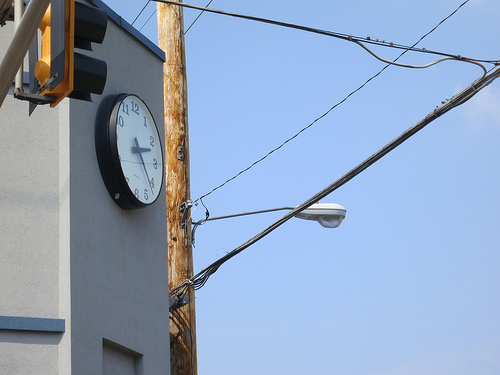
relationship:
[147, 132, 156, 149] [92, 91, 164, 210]
number written on clock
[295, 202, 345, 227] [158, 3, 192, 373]
light on pole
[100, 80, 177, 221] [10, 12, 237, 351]
clock on building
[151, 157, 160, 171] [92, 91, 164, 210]
3 on clock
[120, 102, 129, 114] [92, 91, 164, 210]
number 11 on clock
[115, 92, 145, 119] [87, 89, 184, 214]
numbers on clock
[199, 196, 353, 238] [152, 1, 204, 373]
lamp on pole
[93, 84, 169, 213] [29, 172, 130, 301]
clock on building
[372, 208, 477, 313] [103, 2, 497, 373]
clouds in sky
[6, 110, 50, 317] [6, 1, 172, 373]
gray side in sunlight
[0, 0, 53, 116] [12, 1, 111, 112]
pole holding stop light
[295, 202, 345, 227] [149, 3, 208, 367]
light attached to pole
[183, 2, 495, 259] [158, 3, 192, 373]
power lines on pole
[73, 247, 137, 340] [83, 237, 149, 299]
decoration on wall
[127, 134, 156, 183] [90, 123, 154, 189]
handle on clock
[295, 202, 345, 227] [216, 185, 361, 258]
light on street light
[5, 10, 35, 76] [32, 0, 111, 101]
pole on traffic signal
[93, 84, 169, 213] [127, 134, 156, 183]
clock has handle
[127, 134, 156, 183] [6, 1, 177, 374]
handle on building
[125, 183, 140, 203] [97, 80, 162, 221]
number on clock